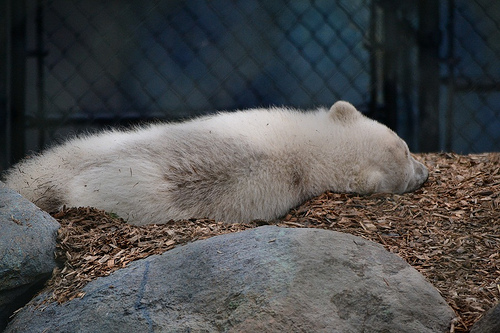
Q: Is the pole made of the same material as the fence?
A: Yes, both the pole and the fence are made of metal.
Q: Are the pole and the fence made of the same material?
A: Yes, both the pole and the fence are made of metal.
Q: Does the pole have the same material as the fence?
A: Yes, both the pole and the fence are made of metal.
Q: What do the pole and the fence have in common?
A: The material, both the pole and the fence are metallic.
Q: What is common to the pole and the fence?
A: The material, both the pole and the fence are metallic.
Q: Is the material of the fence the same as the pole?
A: Yes, both the fence and the pole are made of metal.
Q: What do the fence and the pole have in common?
A: The material, both the fence and the pole are metallic.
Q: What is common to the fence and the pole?
A: The material, both the fence and the pole are metallic.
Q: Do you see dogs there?
A: Yes, there is a dog.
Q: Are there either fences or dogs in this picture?
A: Yes, there is a dog.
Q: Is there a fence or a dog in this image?
A: Yes, there is a dog.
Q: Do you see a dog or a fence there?
A: Yes, there is a dog.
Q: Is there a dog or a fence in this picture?
A: Yes, there is a dog.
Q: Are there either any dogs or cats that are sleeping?
A: Yes, the dog is sleeping.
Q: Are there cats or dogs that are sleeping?
A: Yes, the dog is sleeping.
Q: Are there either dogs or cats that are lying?
A: Yes, the dog is lying.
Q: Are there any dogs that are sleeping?
A: Yes, there is a dog that is sleeping.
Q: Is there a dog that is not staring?
A: Yes, there is a dog that is sleeping.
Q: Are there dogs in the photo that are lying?
A: Yes, there is a dog that is lying.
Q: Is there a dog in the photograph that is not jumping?
A: Yes, there is a dog that is lying.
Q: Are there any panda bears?
A: No, there are no panda bears.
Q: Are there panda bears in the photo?
A: No, there are no panda bears.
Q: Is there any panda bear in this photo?
A: No, there are no panda bears.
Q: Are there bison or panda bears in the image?
A: No, there are no panda bears or bison.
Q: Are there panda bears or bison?
A: No, there are no panda bears or bison.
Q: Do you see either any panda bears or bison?
A: No, there are no panda bears or bison.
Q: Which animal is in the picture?
A: The animal is a dog.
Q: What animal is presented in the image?
A: The animal is a dog.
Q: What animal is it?
A: The animal is a dog.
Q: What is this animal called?
A: This is a dog.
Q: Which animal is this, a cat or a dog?
A: This is a dog.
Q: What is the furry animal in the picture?
A: The animal is a dog.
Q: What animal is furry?
A: The animal is a dog.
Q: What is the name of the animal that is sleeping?
A: The animal is a dog.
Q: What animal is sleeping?
A: The animal is a dog.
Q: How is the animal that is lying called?
A: The animal is a dog.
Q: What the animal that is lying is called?
A: The animal is a dog.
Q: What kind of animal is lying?
A: The animal is a dog.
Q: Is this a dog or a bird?
A: This is a dog.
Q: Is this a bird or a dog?
A: This is a dog.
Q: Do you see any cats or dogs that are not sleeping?
A: No, there is a dog but it is sleeping.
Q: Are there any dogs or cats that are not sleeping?
A: No, there is a dog but it is sleeping.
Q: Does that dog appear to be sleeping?
A: Yes, the dog is sleeping.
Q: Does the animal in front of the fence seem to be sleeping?
A: Yes, the dog is sleeping.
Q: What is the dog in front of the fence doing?
A: The dog is sleeping.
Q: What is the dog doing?
A: The dog is sleeping.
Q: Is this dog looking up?
A: No, the dog is sleeping.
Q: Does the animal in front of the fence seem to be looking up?
A: No, the dog is sleeping.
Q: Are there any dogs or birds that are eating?
A: No, there is a dog but it is sleeping.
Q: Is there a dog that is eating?
A: No, there is a dog but it is sleeping.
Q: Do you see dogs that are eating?
A: No, there is a dog but it is sleeping.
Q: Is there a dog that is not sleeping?
A: No, there is a dog but it is sleeping.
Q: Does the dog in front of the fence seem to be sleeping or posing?
A: The dog is sleeping.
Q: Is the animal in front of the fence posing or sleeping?
A: The dog is sleeping.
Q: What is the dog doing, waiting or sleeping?
A: The dog is sleeping.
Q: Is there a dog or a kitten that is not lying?
A: No, there is a dog but it is lying.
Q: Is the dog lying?
A: Yes, the dog is lying.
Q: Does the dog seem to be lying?
A: Yes, the dog is lying.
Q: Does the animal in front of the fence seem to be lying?
A: Yes, the dog is lying.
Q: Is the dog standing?
A: No, the dog is lying.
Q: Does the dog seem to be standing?
A: No, the dog is lying.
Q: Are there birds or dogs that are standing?
A: No, there is a dog but it is lying.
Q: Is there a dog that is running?
A: No, there is a dog but it is lying.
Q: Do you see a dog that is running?
A: No, there is a dog but it is lying.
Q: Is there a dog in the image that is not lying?
A: No, there is a dog but it is lying.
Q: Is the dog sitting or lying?
A: The dog is lying.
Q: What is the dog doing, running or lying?
A: The dog is lying.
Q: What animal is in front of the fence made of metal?
A: The dog is in front of the fence.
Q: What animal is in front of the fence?
A: The dog is in front of the fence.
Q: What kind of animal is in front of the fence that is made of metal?
A: The animal is a dog.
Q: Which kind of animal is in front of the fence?
A: The animal is a dog.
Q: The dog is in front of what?
A: The dog is in front of the fence.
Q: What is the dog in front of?
A: The dog is in front of the fence.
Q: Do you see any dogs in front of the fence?
A: Yes, there is a dog in front of the fence.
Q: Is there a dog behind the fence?
A: No, the dog is in front of the fence.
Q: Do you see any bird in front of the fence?
A: No, there is a dog in front of the fence.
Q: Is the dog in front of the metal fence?
A: Yes, the dog is in front of the fence.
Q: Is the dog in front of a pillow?
A: No, the dog is in front of the fence.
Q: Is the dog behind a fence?
A: No, the dog is in front of a fence.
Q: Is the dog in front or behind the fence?
A: The dog is in front of the fence.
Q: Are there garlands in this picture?
A: No, there are no garlands.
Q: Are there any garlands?
A: No, there are no garlands.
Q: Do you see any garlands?
A: No, there are no garlands.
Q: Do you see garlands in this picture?
A: No, there are no garlands.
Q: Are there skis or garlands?
A: No, there are no garlands or skis.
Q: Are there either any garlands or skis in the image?
A: No, there are no garlands or skis.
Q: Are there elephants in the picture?
A: No, there are no elephants.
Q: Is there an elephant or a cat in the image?
A: No, there are no elephants or cats.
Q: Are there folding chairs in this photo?
A: No, there are no folding chairs.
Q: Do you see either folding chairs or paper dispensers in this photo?
A: No, there are no folding chairs or paper dispensers.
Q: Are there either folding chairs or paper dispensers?
A: No, there are no folding chairs or paper dispensers.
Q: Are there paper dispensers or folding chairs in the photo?
A: No, there are no folding chairs or paper dispensers.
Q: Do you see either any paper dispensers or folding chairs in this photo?
A: No, there are no folding chairs or paper dispensers.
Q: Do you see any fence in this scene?
A: Yes, there is a fence.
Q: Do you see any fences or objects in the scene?
A: Yes, there is a fence.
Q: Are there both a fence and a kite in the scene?
A: No, there is a fence but no kites.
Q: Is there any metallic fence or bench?
A: Yes, there is a metal fence.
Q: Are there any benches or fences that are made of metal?
A: Yes, the fence is made of metal.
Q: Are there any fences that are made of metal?
A: Yes, there is a fence that is made of metal.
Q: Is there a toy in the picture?
A: No, there are no toys.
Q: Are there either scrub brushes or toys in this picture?
A: No, there are no toys or scrub brushes.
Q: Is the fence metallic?
A: Yes, the fence is metallic.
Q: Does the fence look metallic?
A: Yes, the fence is metallic.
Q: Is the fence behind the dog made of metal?
A: Yes, the fence is made of metal.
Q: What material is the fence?
A: The fence is made of metal.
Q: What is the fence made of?
A: The fence is made of metal.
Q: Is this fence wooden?
A: No, the fence is metallic.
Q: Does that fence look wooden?
A: No, the fence is metallic.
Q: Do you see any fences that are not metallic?
A: No, there is a fence but it is metallic.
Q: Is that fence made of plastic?
A: No, the fence is made of metal.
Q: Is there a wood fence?
A: No, there is a fence but it is made of metal.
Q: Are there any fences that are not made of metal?
A: No, there is a fence but it is made of metal.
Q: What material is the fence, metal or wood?
A: The fence is made of metal.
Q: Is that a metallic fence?
A: Yes, that is a metallic fence.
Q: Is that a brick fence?
A: No, that is a metallic fence.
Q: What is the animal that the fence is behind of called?
A: The animal is a dog.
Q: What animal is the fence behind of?
A: The fence is behind the dog.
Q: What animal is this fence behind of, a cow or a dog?
A: The fence is behind a dog.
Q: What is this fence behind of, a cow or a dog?
A: The fence is behind a dog.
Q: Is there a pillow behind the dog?
A: No, there is a fence behind the dog.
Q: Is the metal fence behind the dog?
A: Yes, the fence is behind the dog.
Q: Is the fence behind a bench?
A: No, the fence is behind the dog.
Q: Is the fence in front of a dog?
A: No, the fence is behind a dog.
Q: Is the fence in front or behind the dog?
A: The fence is behind the dog.